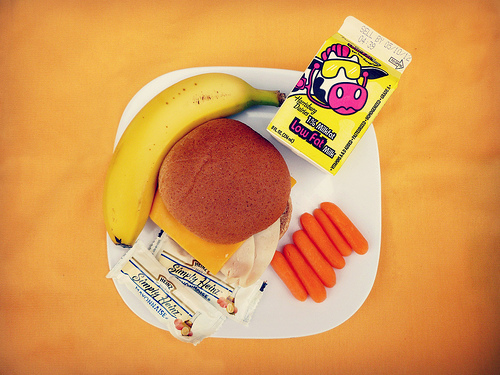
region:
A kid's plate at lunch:
[61, 40, 452, 347]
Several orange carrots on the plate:
[262, 205, 373, 305]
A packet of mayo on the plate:
[105, 251, 266, 346]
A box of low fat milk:
[269, 5, 413, 178]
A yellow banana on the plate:
[74, 42, 225, 263]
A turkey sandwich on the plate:
[146, 108, 293, 292]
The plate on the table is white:
[86, 36, 428, 354]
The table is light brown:
[1, 10, 86, 373]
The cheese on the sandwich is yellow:
[136, 195, 233, 279]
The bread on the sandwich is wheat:
[131, 120, 301, 253]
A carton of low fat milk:
[265, 14, 413, 178]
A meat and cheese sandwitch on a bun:
[147, 116, 296, 288]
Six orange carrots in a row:
[267, 197, 368, 303]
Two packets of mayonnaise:
[105, 224, 267, 349]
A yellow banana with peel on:
[101, 71, 286, 248]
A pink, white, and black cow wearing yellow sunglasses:
[289, 43, 386, 115]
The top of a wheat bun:
[157, 116, 291, 245]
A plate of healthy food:
[102, 15, 414, 345]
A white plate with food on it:
[104, 65, 381, 340]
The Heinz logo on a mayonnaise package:
[155, 272, 177, 292]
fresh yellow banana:
[91, 58, 216, 250]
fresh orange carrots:
[275, 198, 384, 318]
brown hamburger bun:
[174, 128, 279, 228]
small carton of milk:
[266, 2, 431, 179]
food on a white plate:
[88, 23, 435, 350]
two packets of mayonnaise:
[111, 228, 257, 348]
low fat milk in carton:
[274, 5, 429, 167]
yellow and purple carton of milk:
[269, 6, 426, 177]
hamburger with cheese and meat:
[152, 125, 301, 280]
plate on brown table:
[68, 22, 453, 364]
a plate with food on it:
[78, 27, 424, 342]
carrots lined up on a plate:
[271, 201, 373, 304]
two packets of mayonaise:
[97, 237, 290, 348]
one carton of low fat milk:
[276, 14, 417, 190]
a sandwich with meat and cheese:
[156, 128, 304, 293]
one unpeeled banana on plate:
[110, 47, 290, 279]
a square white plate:
[91, 51, 401, 353]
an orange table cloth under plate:
[3, 0, 498, 373]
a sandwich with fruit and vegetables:
[106, 67, 377, 310]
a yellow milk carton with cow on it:
[258, 17, 421, 172]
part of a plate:
[333, 250, 389, 301]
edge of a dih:
[255, 314, 285, 351]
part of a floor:
[381, 198, 423, 268]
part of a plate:
[278, 291, 307, 317]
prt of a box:
[290, 110, 355, 235]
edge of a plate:
[252, 310, 289, 362]